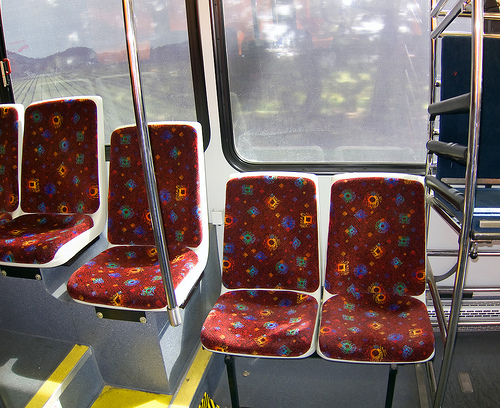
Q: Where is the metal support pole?
A: Between the seats.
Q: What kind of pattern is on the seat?
A: Circles and Boxes.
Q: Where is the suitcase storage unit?
A: On the right.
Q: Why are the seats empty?
A: No people on bus.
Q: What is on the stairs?
A: Yellow caution tape.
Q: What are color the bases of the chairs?
A: White.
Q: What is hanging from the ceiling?
A: Support pole.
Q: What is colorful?
A: The seat.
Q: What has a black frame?
A: The window.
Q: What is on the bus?
A: Brown multicolored seats.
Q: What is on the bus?
A: The luggage rack.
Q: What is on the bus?
A: The back window.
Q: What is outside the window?
A: The field.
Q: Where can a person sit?
A: Chairs.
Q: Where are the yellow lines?
A: Floor.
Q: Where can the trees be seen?
A: Through the back window.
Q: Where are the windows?
A: Behind The seats.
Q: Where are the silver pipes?
A: Beside the seats.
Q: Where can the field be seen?
A: Through the window on the left.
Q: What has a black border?
A: Windows.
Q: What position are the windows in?
A: Closed.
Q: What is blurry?
A: Scenery through the window.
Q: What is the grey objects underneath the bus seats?
A: Floor.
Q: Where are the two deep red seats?
A: On bus.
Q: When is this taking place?
A: Daytime.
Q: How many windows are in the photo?
A: Two.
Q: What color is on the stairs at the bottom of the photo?
A: Yellow.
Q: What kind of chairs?
A: Red, yellow, green and blue.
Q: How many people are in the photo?
A: None.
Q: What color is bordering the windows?
A: Black.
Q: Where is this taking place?
A: On the bus.